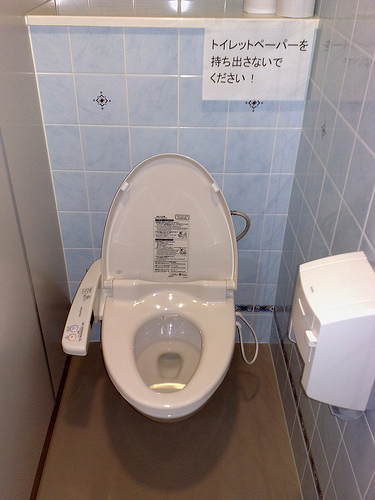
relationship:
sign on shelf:
[203, 18, 316, 103] [24, 1, 319, 25]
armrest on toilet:
[60, 259, 100, 355] [59, 150, 237, 425]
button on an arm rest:
[67, 333, 76, 339] [60, 258, 100, 359]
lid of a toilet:
[99, 151, 239, 290] [59, 150, 237, 425]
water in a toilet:
[148, 344, 190, 374] [88, 150, 239, 424]